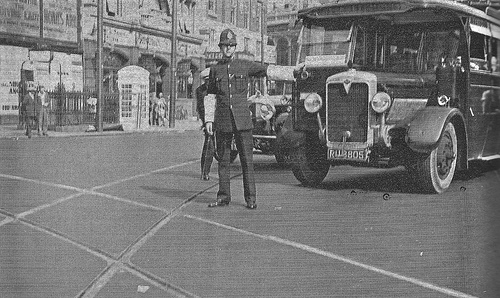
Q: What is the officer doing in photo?
A: Directing traffic.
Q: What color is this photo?
A: Black and white.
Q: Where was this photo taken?
A: On a city street.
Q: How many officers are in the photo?
A: One.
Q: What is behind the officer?
A: Vehicles.